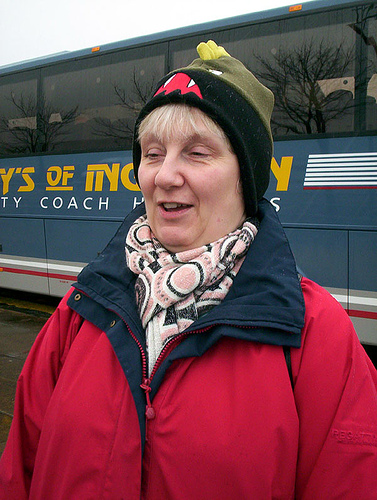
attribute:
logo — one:
[326, 422, 376, 452]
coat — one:
[12, 223, 372, 490]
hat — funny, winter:
[134, 43, 291, 180]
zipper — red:
[123, 356, 166, 417]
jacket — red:
[0, 195, 364, 496]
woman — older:
[1, 37, 364, 494]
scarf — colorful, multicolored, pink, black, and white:
[123, 211, 260, 378]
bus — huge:
[1, 1, 364, 343]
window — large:
[168, 5, 359, 137]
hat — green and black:
[132, 38, 277, 222]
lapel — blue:
[64, 192, 303, 404]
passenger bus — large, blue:
[1, 0, 364, 342]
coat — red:
[0, 196, 364, 496]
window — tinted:
[170, 19, 359, 138]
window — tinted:
[38, 50, 166, 154]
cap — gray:
[132, 37, 278, 220]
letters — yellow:
[1, 152, 294, 193]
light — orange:
[284, 0, 305, 14]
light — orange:
[87, 43, 100, 51]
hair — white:
[132, 104, 224, 143]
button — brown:
[71, 290, 82, 300]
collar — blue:
[64, 200, 303, 346]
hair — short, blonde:
[131, 102, 206, 143]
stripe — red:
[0, 261, 376, 319]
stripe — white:
[0, 257, 376, 306]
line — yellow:
[0, 290, 59, 316]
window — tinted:
[362, 13, 375, 138]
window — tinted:
[0, 74, 35, 154]